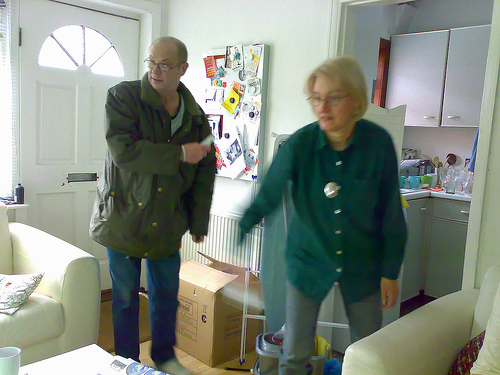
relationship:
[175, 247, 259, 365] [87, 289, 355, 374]
box on floor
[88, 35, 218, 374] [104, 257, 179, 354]
guy wearing jeans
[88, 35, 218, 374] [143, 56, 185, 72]
guy wearing eye glasses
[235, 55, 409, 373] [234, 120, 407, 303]
lady wearing shirt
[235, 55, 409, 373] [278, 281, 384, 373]
lady wearing pants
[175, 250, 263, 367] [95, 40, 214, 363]
box behind people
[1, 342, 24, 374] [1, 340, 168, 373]
cup above table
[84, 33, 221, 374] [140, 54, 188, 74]
guy wearing glasses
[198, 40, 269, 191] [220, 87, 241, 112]
wall board with note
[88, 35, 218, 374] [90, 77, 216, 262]
guy wearing jacket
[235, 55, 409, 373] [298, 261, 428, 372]
lady wearing pants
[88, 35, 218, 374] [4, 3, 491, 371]
guy inside house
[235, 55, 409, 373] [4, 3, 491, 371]
lady inside house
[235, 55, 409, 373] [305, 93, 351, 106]
lady wearing glasses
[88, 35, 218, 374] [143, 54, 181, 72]
guy wearing eye glasses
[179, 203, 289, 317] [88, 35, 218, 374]
rack behind guy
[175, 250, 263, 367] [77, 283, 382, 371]
box on floor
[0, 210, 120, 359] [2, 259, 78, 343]
couch has pillow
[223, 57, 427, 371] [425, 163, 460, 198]
lady has glasses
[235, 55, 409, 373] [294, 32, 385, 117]
lady has hair